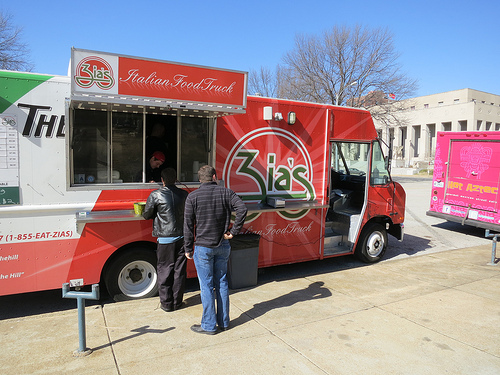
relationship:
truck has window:
[3, 44, 405, 297] [68, 99, 215, 190]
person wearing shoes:
[184, 163, 246, 337] [192, 317, 234, 335]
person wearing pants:
[184, 163, 246, 337] [190, 237, 234, 332]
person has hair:
[184, 163, 246, 337] [197, 165, 221, 181]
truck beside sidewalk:
[3, 44, 405, 297] [0, 245, 496, 374]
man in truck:
[144, 150, 166, 181] [3, 44, 405, 297]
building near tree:
[367, 84, 499, 181] [279, 28, 405, 148]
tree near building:
[279, 28, 405, 148] [367, 84, 499, 181]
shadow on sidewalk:
[226, 281, 335, 324] [0, 245, 496, 374]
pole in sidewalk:
[59, 280, 107, 354] [0, 245, 496, 374]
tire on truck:
[105, 244, 169, 306] [3, 44, 405, 297]